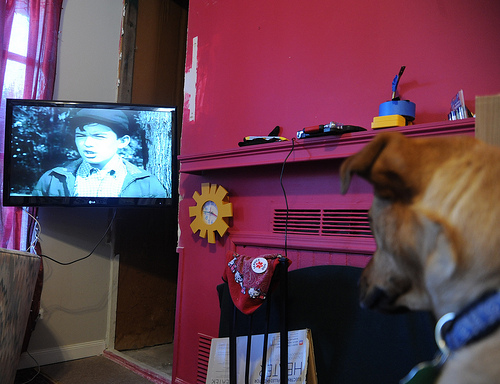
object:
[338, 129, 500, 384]
dog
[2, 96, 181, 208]
television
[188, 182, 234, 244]
clock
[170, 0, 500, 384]
wall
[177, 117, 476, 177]
mantle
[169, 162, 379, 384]
fireplace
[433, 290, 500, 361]
collar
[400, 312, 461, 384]
ring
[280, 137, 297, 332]
cord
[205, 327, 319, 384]
bag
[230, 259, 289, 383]
straps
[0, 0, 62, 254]
curtains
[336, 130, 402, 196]
ear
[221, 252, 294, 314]
bandana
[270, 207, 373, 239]
grates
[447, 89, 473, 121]
items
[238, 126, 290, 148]
items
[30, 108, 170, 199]
man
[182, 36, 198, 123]
patch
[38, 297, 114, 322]
shadow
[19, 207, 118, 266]
cord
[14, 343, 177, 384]
floor